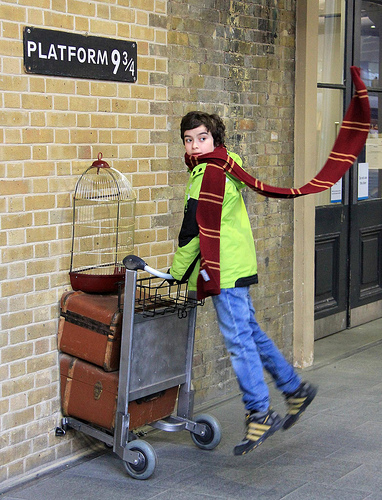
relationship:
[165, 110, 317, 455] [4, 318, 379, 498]
kid on ground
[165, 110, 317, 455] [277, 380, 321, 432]
kid has a shoe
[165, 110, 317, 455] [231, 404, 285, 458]
kid has a shoe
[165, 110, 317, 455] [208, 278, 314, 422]
kid wearing jeans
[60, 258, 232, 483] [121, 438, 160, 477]
object has a wheel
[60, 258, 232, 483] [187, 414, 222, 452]
object has a wheel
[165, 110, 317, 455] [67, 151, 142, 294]
kid beside cage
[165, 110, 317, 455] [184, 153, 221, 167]
kid has a neck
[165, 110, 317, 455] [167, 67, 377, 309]
kid has a scarf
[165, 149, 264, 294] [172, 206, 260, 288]
jacket has black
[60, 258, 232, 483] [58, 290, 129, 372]
rack has suitcase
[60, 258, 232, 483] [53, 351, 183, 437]
rack has suitcase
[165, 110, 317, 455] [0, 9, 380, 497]
kid in air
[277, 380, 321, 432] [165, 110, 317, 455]
shoe on kid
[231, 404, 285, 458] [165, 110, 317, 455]
shoe on kid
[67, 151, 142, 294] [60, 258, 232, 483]
cage on top of object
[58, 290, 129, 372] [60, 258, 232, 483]
suitcase on object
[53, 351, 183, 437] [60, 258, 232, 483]
suitcase on object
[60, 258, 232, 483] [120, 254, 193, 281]
object has a handle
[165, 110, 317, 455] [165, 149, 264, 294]
kid has a jacket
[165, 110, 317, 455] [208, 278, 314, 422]
kid has jeans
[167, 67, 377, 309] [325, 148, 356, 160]
scarf has stripe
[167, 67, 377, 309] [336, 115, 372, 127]
scarf has a stripe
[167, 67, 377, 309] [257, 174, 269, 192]
scarf has a stripe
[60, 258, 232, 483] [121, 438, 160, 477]
object has wheel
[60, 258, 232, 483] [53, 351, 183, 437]
object for luggage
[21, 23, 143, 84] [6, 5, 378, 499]
sign on platform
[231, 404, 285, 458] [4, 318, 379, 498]
foot off ground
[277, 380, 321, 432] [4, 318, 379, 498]
shoe off ground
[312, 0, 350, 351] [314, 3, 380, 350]
door in set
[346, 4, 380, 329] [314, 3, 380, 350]
door in set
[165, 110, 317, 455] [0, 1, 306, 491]
kid entering wall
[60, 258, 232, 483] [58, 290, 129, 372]
object has suitcase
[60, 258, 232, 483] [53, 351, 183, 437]
object has suitcase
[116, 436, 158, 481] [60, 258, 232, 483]
object from metal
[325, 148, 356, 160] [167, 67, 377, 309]
stripe on scarf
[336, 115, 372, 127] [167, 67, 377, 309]
stripe on scarf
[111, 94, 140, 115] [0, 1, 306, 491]
brick in wall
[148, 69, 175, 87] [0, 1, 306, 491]
brick in wall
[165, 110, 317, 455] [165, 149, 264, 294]
kid wearing jacket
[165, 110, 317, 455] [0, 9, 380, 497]
kid flying in air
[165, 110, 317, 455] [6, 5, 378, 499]
kid entering platform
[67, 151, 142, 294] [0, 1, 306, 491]
cage entering wall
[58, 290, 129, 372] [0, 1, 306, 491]
suitcase entering wall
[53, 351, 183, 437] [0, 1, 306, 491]
suitcase entering wall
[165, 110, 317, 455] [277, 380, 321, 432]
kid wearing shoe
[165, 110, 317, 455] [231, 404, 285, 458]
kid wearing shoe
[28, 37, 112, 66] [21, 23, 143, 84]
writing on sign